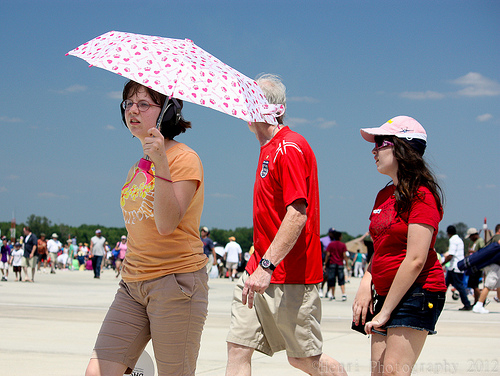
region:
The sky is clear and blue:
[266, 5, 481, 76]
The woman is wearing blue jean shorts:
[363, 285, 450, 337]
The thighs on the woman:
[364, 322, 429, 374]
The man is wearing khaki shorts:
[226, 266, 327, 360]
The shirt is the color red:
[240, 124, 330, 291]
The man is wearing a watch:
[256, 252, 280, 274]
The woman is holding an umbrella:
[63, 14, 288, 216]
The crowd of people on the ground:
[1, 221, 128, 285]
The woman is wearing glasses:
[116, 93, 167, 118]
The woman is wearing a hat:
[355, 110, 431, 151]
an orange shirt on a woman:
[118, 138, 205, 280]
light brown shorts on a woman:
[94, 262, 208, 374]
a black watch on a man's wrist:
[254, 257, 277, 272]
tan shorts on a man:
[225, 270, 327, 360]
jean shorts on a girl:
[367, 286, 449, 331]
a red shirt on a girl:
[366, 184, 450, 293]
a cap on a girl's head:
[356, 113, 429, 140]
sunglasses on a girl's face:
[372, 136, 398, 148]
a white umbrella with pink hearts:
[65, 31, 280, 175]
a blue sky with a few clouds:
[0, 0, 497, 241]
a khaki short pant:
[98, 274, 205, 374]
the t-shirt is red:
[365, 187, 445, 287]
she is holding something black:
[350, 298, 385, 332]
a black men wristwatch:
[260, 259, 272, 269]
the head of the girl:
[370, 125, 426, 177]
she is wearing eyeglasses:
[121, 98, 156, 109]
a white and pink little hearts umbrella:
[65, 30, 277, 127]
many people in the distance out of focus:
[5, 230, 130, 285]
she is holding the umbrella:
[139, 100, 171, 173]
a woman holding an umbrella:
[66, 30, 276, 233]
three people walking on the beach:
[85, 76, 445, 373]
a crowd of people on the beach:
[1, 223, 499, 312]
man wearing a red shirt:
[246, 125, 323, 285]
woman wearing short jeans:
[376, 285, 443, 335]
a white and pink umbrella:
[66, 32, 283, 127]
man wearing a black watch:
[258, 257, 274, 272]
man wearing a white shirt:
[222, 240, 242, 260]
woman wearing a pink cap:
[360, 114, 427, 141]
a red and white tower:
[8, 222, 17, 244]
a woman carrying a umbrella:
[65, 23, 280, 372]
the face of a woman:
[116, 90, 153, 132]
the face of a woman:
[367, 136, 390, 175]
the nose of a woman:
[123, 101, 143, 118]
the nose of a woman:
[369, 144, 383, 156]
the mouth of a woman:
[125, 115, 145, 127]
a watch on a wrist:
[257, 254, 279, 274]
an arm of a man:
[237, 167, 311, 312]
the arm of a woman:
[372, 207, 438, 336]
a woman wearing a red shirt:
[354, 108, 456, 286]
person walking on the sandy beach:
[77, 62, 209, 372]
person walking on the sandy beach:
[230, 77, 335, 372]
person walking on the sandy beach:
[346, 111, 453, 367]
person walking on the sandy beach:
[436, 220, 472, 316]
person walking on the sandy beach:
[327, 227, 352, 307]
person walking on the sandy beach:
[85, 220, 106, 277]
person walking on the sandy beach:
[43, 233, 60, 273]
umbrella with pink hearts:
[101, 39, 210, 76]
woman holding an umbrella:
[88, 50, 215, 350]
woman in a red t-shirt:
[364, 115, 438, 366]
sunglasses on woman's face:
[373, 137, 395, 151]